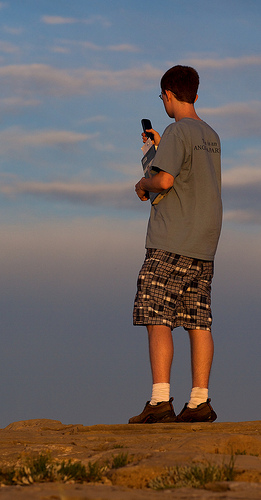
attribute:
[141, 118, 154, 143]
phone — black, rectangular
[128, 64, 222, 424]
boy — standing, young, looking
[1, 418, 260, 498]
ground — stone, stoney, brown, flat, rocky, tan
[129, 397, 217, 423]
shoes — brown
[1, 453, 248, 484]
grass — green, dry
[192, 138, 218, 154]
writing — black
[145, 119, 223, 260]
shirt — bluish-gray, gray, dark grey, grey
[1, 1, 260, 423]
sky — blue, cloudy, grey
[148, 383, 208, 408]
socks — white, rolled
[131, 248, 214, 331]
shorts — black, white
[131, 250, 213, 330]
squares — black, white, gray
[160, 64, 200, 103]
hair — short, black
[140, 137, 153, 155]
paper — white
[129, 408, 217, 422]
soles — dark brown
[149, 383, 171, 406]
sock — white, long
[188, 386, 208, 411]
sock — white, long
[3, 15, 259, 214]
clouds — white